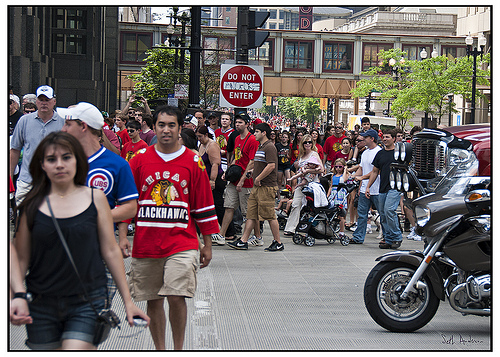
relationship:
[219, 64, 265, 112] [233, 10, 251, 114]
sign on pole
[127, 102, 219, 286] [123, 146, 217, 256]
man in shirt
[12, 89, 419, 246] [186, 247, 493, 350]
crowd in street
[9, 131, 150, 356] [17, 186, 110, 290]
woman in tanktop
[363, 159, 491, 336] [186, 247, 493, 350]
bike on street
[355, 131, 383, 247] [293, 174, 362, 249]
man with stroller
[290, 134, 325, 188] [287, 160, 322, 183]
woman with baby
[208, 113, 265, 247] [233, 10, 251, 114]
man near pole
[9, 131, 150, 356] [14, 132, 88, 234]
woman with hair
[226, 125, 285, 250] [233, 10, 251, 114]
man near pole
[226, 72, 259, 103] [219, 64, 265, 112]
words on sign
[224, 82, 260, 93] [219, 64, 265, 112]
graffiti on sign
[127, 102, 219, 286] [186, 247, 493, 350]
man on street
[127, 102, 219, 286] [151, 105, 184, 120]
man with hair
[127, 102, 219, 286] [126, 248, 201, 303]
man in shorts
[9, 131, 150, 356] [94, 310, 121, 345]
woman with purse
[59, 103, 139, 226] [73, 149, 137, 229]
man in jersey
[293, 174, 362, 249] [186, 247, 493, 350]
stroller on street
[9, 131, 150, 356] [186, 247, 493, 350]
woman on street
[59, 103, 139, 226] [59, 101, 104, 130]
man in hat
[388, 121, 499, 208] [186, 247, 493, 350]
truck on street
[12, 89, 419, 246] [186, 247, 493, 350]
crowd on street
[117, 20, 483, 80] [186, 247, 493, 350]
skyway over street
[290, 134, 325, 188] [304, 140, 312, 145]
woman with glasses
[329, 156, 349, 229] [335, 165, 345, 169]
girl with glasses